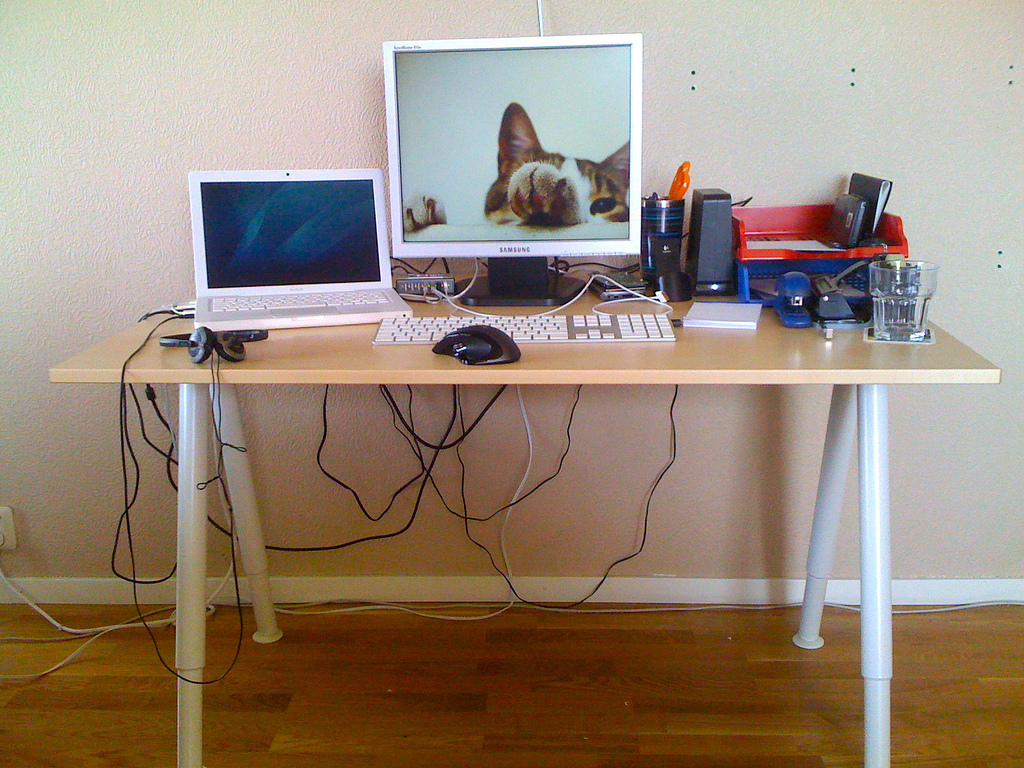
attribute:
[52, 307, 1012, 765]
desk — large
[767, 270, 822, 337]
stapler — blue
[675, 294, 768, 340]
paper pad — white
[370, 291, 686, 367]
keyboard —  thin and white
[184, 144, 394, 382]
laptop — open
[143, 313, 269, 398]
headphones — black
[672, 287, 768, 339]
pad — white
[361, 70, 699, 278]
monitor — large 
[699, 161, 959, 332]
inboxes — red, blue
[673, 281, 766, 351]
paper — white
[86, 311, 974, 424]
desk — wooden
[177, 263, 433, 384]
laptop — white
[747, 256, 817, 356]
stapler — blue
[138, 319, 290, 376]
headphones — black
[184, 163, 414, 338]
laptop — white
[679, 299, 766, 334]
paper notepad — white